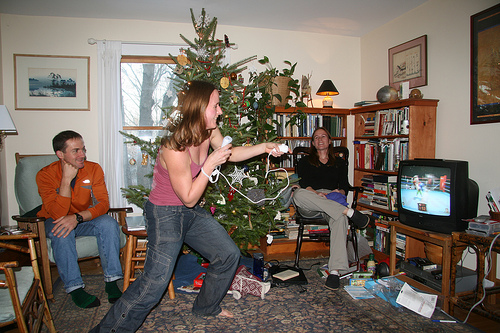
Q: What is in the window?
A: Christmas tree.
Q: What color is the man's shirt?
A: Red.